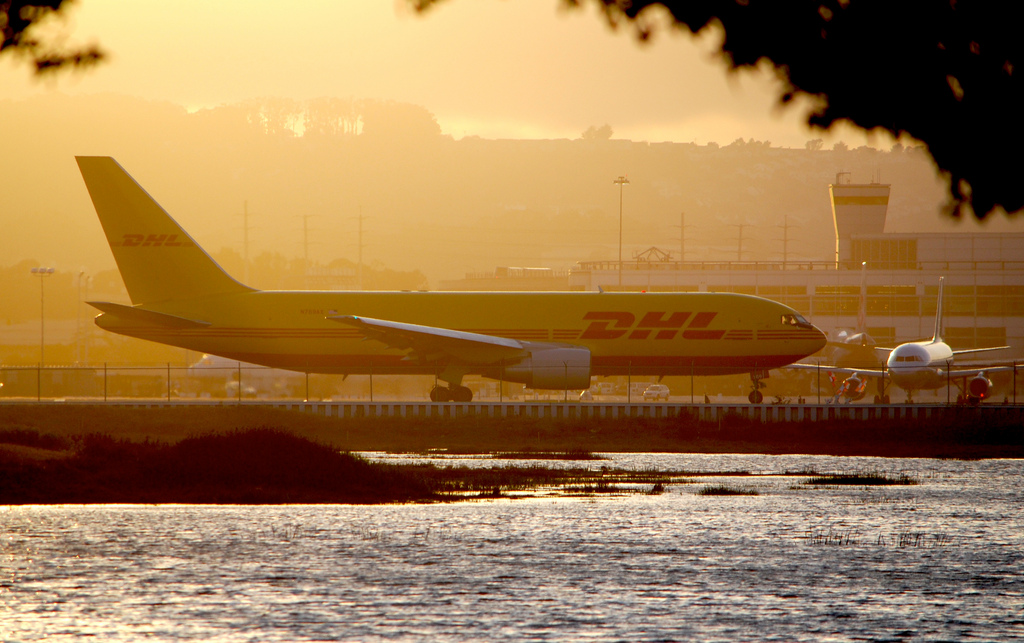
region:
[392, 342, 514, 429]
The rear wheels on an airplane/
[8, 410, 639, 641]
Sunlight reflected on the water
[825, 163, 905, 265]
the airport tower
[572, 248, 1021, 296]
the top of the airport building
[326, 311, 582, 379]
A white wing of the yellow plane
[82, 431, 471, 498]
grass along the bank of the river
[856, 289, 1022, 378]
Another plane preparing to take off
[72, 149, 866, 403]
a yellow airplane with red lettering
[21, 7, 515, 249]
smoke or smog in the sky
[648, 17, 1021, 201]
The edge of a tree in the foreground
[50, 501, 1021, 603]
the bright looking water in the foreground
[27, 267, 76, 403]
one of the airport runway lights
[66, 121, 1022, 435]
Two planes at an airport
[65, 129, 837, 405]
A plane at an airport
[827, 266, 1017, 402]
A plane at an airport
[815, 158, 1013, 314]
Traffic control tower at an aiport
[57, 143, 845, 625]
Plane with water in the foreground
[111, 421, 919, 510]
Shallow shoreline and vegetation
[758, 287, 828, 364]
Pilot in plane cockpit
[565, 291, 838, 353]
Log on plane fuselage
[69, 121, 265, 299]
Logo on plane tail fin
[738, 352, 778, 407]
Front landing wheels on a plane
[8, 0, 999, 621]
Scene of an airport.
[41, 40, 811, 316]
It's sky is hazy.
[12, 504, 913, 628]
Water is near the airport.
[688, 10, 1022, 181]
Some foliage on the right side.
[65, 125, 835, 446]
A yellow airplane.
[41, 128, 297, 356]
Lettering on the tail of the airplane.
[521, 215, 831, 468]
The letters DHL on front of plane.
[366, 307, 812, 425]
The wheels are down on the plane.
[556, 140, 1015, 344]
An airport in the background.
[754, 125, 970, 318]
The control tower of the airport.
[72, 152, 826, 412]
a yellow DHL airplane on a runway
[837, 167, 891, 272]
an airport control tower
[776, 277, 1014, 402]
a white plane at an airport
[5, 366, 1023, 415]
chain link fence surrounding airport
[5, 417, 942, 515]
vegetation in the water outside the airport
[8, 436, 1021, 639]
lake or river outside the airport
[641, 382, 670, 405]
car at airport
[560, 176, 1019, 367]
airport terminal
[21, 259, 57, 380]
light in the airport parking lot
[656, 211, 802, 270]
power line poles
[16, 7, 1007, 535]
A scene at an airport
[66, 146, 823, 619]
An airplane with water in front of it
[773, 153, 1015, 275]
Flight control tower at an airport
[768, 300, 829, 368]
Crew visible in airplane cockpit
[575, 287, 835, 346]
Logo on an airplane fuselage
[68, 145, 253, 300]
Logo on airplane tail fin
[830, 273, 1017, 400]
Semi-frontal view of an airplne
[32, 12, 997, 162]
Horizon and treeline shrouded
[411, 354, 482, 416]
Deployed wheels on an airplane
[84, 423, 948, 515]
Shallow water and shoreline vegetation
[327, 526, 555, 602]
ripples on the water's surface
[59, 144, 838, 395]
large yellow plane near the water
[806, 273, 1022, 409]
plane in the distance facing away from building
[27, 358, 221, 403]
fence behind the yellow plane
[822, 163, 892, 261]
an airport control tower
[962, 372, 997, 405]
appears to be a red light on the plane's engine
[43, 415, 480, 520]
small island in the midst of the water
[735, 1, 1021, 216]
foliage in the foreground